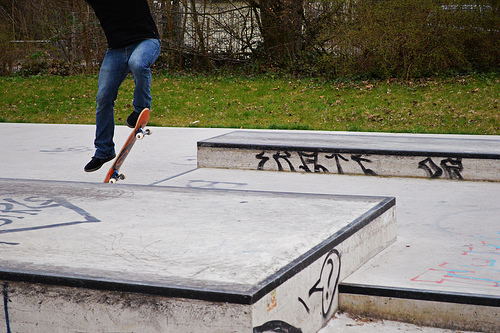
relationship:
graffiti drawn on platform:
[257, 151, 376, 174] [197, 130, 500, 181]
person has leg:
[85, 1, 162, 171] [93, 50, 125, 152]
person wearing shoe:
[85, 1, 162, 171] [85, 150, 118, 171]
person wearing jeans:
[85, 1, 162, 171] [95, 38, 160, 159]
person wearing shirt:
[85, 1, 162, 171] [85, 1, 160, 48]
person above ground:
[85, 1, 162, 171] [2, 74, 500, 332]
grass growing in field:
[0, 75, 499, 134] [0, 53, 499, 135]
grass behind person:
[0, 75, 499, 134] [85, 1, 162, 171]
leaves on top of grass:
[332, 77, 469, 94] [0, 75, 499, 134]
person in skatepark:
[85, 1, 162, 171] [2, 122, 500, 331]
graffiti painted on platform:
[418, 155, 464, 179] [197, 130, 500, 181]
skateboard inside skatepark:
[105, 107, 154, 184] [2, 122, 500, 331]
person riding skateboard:
[85, 1, 162, 171] [105, 107, 154, 184]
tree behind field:
[260, 3, 306, 57] [0, 53, 499, 135]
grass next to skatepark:
[0, 75, 499, 134] [2, 122, 500, 331]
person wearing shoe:
[85, 1, 162, 171] [127, 108, 140, 127]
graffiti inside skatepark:
[298, 248, 343, 319] [2, 122, 500, 331]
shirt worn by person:
[85, 1, 160, 48] [85, 1, 162, 171]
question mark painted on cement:
[327, 259, 335, 299] [254, 201, 398, 332]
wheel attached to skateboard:
[134, 131, 143, 140] [105, 107, 154, 184]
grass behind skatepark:
[0, 75, 499, 134] [2, 122, 500, 331]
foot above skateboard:
[84, 151, 116, 172] [105, 107, 154, 184]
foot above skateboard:
[125, 110, 142, 127] [105, 107, 154, 184]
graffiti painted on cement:
[298, 248, 343, 319] [254, 201, 398, 332]